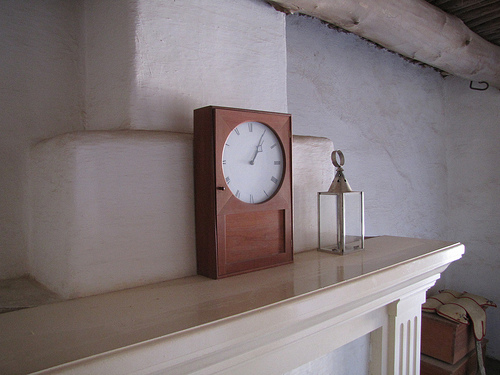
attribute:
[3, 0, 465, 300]
wall — white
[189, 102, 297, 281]
clock — wooden, small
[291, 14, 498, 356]
wall — white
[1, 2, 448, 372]
wall — white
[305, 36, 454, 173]
wall — white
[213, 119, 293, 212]
clock — is wooden, is white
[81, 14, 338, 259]
chimney — part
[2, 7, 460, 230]
wall — is white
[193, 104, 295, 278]
frame — brown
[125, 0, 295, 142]
wall — white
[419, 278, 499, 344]
mats — are red, are yellow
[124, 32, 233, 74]
wall — white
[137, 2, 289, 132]
wall — white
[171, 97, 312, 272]
clock — little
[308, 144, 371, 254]
decoration — tiny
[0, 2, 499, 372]
wall — white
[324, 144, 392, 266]
thing — silver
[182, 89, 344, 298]
cabinet — wooden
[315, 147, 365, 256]
box — is metal, is small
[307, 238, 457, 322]
concrete — is white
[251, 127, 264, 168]
clock arm — is black